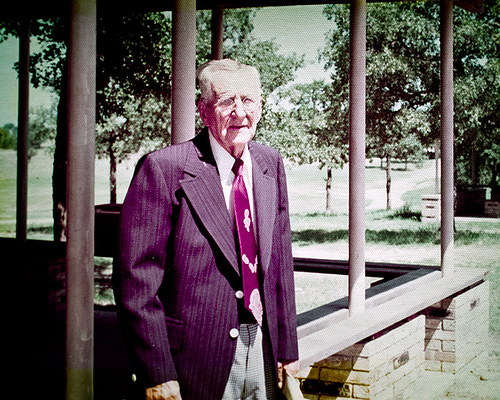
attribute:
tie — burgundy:
[227, 159, 456, 219]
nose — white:
[228, 93, 246, 121]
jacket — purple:
[119, 118, 299, 398]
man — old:
[126, 53, 303, 398]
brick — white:
[425, 326, 462, 341]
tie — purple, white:
[221, 155, 263, 332]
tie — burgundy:
[227, 156, 267, 330]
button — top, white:
[230, 287, 245, 302]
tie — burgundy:
[208, 149, 285, 321]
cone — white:
[246, 284, 272, 331]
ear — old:
[193, 93, 211, 129]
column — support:
[64, 2, 94, 399]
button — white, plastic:
[217, 320, 238, 344]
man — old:
[95, 45, 402, 396]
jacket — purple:
[101, 126, 338, 397]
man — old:
[113, 59, 299, 399]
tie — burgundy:
[232, 158, 263, 328]